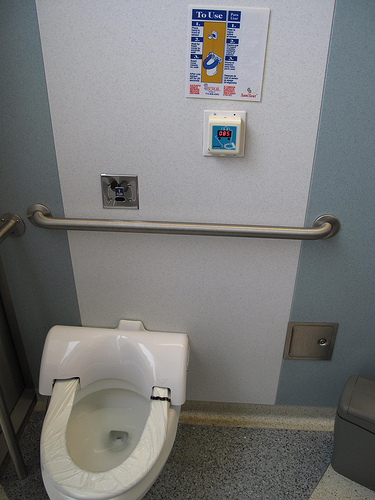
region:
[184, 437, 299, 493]
Black and white floor next to the toilet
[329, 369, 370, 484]
Gray wastebasket to the right of the toilet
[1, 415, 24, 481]
Vertical silver bar to the left of the toilet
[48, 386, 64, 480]
Covered white toilet seat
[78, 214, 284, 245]
Horizontal silver bar above the toilet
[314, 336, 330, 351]
Keyhole in the silver square on the wall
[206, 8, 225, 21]
The word 'Use' in the sign on the wall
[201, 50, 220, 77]
Picture of a toilet in the sign on the wall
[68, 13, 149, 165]
White portion of the wall behind the toilet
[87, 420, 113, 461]
Water inside of the toilet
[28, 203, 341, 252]
long metal safety bathroom railing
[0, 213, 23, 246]
metal safety bathroom railing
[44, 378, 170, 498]
clear plastic bathroom hygiene wrapping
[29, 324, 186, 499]
low white ceramic bathroom toilet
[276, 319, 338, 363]
square shiny metal door with lock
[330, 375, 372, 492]
small plastic gray trashcan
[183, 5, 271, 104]
red blue and yellow bathroom sign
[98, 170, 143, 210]
metal help pull for emergencies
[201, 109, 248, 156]
plastic white hanger with red numbers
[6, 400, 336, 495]
gray and black speckled floor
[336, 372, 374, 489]
Gray trash can to the right of the toilet.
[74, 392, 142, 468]
Water inside of the white toilet.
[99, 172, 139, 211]
Motion sensor display on wall to flush the toilet.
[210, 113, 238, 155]
White and blue digital box mounted on wall above the toilet.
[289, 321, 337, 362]
Silver square with key hole on wall.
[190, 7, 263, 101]
Instruction paper on how to use the toilet on wall.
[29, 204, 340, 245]
Metal bar above the toilet.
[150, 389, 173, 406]
Black tier on the toilet seat.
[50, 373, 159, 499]
Clear plastic wrapped around the toilet seat.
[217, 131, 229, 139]
Numbers on digital display box on the wall.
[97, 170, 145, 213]
a silver back-plated button for toilet flushing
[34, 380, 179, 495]
a toilet seat wrapped in protective plastic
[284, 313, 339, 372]
a small silver door on the wall with a key lock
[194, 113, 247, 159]
a white box with a red digital display on it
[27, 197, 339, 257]
a long grey steel bar for holding to get off the toilet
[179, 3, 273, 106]
a sign on the wall with instructions on how to use the toilet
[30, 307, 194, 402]
the base of the toilet attached to the wall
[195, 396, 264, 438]
a filthy baseboard in the bathroom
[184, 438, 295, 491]
speckled laminate flooring in the bathroom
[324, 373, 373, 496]
a small grey trash bin near the toilet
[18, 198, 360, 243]
Brushed metal safety bar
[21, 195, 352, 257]
Stainless steel safety bar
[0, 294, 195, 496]
White plastic toilet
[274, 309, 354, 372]
Silver metal access panel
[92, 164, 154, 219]
Silver metal toilet flush button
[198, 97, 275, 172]
Plastic bathroom thermostat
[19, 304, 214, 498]
White toilet with plastic seat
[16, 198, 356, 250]
Silver metal bathroom grab bar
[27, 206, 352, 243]
Silver metal grab bar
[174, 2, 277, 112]
White sign with blue writing